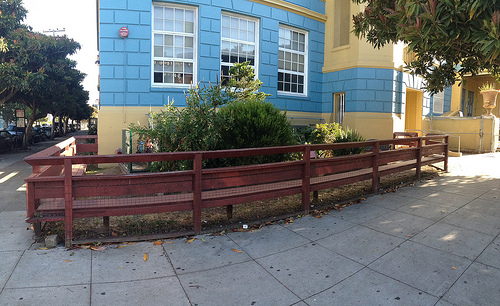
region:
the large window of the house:
[150, 3, 194, 94]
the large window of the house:
[217, 11, 260, 98]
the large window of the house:
[280, 24, 307, 96]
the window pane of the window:
[155, 72, 162, 82]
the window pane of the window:
[162, 71, 174, 85]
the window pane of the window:
[175, 73, 182, 82]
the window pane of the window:
[185, 72, 194, 86]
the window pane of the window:
[220, 65, 229, 76]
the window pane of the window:
[221, 76, 230, 86]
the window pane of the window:
[277, 70, 284, 81]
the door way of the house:
[406, 86, 424, 143]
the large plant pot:
[480, 88, 497, 116]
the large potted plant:
[477, 81, 495, 112]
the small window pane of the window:
[154, 34, 165, 45]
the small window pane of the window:
[163, 33, 174, 48]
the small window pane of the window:
[174, 33, 183, 48]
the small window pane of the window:
[292, 56, 299, 73]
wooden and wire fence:
[23, 126, 460, 249]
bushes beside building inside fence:
[162, 87, 323, 176]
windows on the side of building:
[116, 0, 310, 100]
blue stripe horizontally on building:
[53, 11, 468, 125]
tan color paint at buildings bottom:
[81, 98, 496, 148]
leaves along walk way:
[27, 175, 479, 265]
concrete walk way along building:
[11, 195, 498, 303]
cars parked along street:
[0, 110, 79, 143]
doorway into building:
[399, 76, 441, 167]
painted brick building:
[66, 7, 495, 159]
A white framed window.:
[150, 8, 200, 91]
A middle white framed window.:
[218, 13, 261, 94]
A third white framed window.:
[275, 26, 309, 98]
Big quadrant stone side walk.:
[5, 192, 499, 302]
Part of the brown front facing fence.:
[26, 131, 448, 241]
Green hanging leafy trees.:
[0, 0, 92, 130]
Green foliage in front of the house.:
[128, 61, 358, 161]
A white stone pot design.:
[478, 86, 498, 118]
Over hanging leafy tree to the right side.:
[352, 0, 498, 94]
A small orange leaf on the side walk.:
[137, 251, 152, 265]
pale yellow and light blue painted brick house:
[89, 0, 497, 178]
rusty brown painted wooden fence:
[17, 125, 457, 262]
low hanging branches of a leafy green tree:
[343, 1, 498, 106]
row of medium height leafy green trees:
[2, 0, 90, 155]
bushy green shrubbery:
[123, 55, 373, 172]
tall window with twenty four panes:
[145, 2, 202, 90]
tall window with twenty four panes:
[214, 2, 264, 97]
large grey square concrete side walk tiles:
[3, 167, 498, 304]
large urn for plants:
[473, 75, 498, 123]